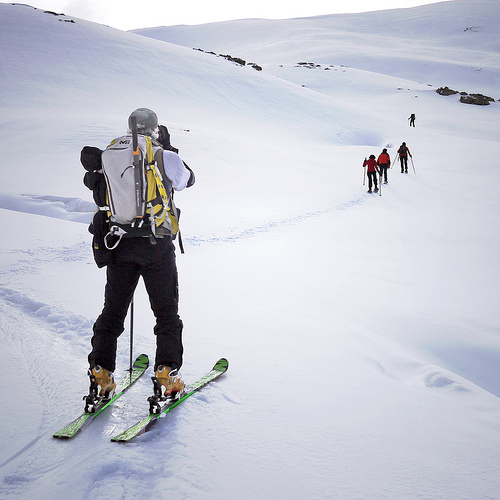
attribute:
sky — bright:
[0, 0, 449, 43]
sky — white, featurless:
[188, 0, 228, 30]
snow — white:
[344, 255, 397, 317]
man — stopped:
[81, 108, 196, 394]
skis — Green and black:
[111, 357, 228, 442]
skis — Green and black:
[53, 355, 147, 438]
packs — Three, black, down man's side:
[75, 142, 114, 243]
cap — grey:
[129, 107, 158, 133]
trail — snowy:
[332, 124, 414, 228]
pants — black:
[102, 221, 269, 371]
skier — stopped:
[76, 116, 234, 408]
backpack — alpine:
[76, 118, 190, 277]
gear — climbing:
[57, 112, 219, 318]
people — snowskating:
[52, 97, 422, 444]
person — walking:
[394, 138, 410, 173]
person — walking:
[377, 144, 389, 184]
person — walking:
[362, 155, 381, 195]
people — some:
[361, 138, 425, 194]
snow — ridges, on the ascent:
[237, 101, 339, 217]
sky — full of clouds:
[35, 1, 412, 22]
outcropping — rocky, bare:
[436, 85, 496, 108]